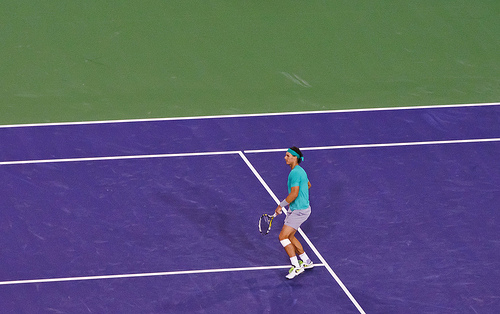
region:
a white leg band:
[278, 236, 297, 246]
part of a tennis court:
[314, 0, 499, 313]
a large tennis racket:
[255, 208, 285, 236]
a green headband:
[285, 146, 304, 161]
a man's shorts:
[282, 208, 309, 224]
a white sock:
[288, 255, 302, 266]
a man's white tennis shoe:
[280, 260, 307, 277]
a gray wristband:
[278, 197, 290, 207]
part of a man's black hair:
[292, 145, 303, 155]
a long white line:
[0, 147, 242, 169]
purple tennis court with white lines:
[0, 100, 498, 307]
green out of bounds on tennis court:
[0, 0, 497, 127]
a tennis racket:
[260, 210, 280, 234]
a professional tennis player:
[257, 144, 312, 280]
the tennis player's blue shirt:
[285, 170, 308, 207]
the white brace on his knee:
[278, 236, 289, 247]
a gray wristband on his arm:
[277, 196, 287, 207]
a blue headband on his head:
[287, 148, 301, 161]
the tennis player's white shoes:
[283, 260, 314, 277]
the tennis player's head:
[283, 145, 300, 166]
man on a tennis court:
[250, 138, 332, 292]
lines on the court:
[8, 82, 498, 312]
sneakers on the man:
[266, 246, 320, 296]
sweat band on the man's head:
[278, 140, 308, 170]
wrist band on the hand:
[275, 198, 292, 211]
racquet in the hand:
[247, 201, 287, 241]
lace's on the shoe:
[287, 263, 295, 275]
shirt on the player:
[261, 157, 321, 213]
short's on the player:
[270, 200, 318, 234]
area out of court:
[1, 18, 488, 110]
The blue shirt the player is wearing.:
[287, 166, 311, 206]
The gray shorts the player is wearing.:
[280, 208, 310, 228]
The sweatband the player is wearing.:
[280, 196, 286, 208]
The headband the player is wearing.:
[285, 148, 303, 160]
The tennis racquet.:
[256, 212, 278, 232]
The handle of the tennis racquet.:
[268, 208, 280, 220]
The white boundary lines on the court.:
[1, 116, 483, 311]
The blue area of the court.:
[2, 97, 498, 305]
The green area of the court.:
[3, 1, 496, 120]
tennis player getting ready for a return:
[257, 148, 317, 277]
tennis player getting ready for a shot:
[256, 147, 314, 278]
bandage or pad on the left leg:
[277, 235, 292, 250]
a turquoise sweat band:
[285, 145, 305, 159]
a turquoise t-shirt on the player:
[286, 165, 310, 207]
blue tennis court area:
[4, 105, 497, 311]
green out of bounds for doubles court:
[0, 0, 498, 122]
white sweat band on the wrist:
[278, 198, 289, 209]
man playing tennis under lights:
[273, 143, 313, 280]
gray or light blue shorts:
[283, 205, 310, 230]